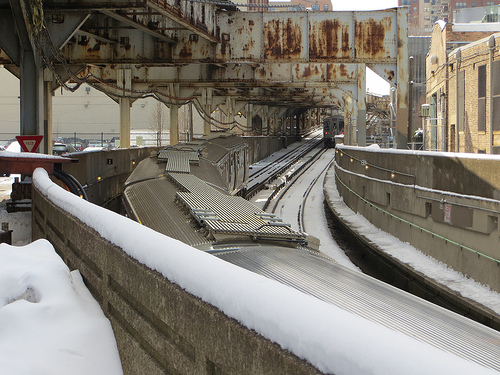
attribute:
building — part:
[423, 19, 499, 154]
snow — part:
[0, 235, 123, 374]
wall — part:
[32, 167, 499, 373]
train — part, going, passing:
[321, 114, 344, 147]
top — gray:
[325, 111, 345, 120]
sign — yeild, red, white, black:
[16, 134, 45, 153]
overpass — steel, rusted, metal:
[1, 0, 409, 211]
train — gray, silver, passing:
[117, 134, 500, 374]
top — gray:
[119, 129, 498, 373]